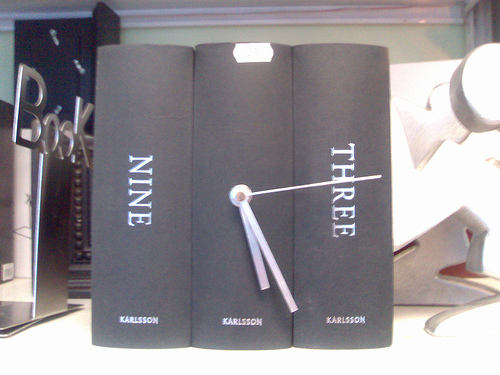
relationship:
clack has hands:
[224, 169, 293, 258] [203, 173, 308, 273]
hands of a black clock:
[203, 173, 308, 273] [91, 43, 393, 345]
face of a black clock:
[185, 161, 314, 240] [91, 43, 393, 345]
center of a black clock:
[203, 126, 296, 325] [91, 43, 393, 345]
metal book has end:
[85, 45, 216, 267] [105, 122, 197, 198]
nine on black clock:
[119, 145, 169, 240] [91, 43, 393, 345]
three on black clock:
[318, 140, 364, 240] [91, 43, 393, 345]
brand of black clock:
[193, 181, 346, 241] [91, 43, 393, 345]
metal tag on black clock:
[198, 302, 276, 341] [91, 43, 393, 345]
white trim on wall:
[393, 50, 498, 103] [393, 27, 433, 49]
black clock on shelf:
[91, 43, 393, 345] [60, 262, 464, 339]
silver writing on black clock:
[119, 145, 169, 240] [91, 43, 393, 345]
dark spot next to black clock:
[153, 56, 237, 119] [91, 43, 393, 345]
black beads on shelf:
[72, 280, 331, 341] [60, 262, 464, 339]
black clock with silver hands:
[145, 69, 283, 165] [224, 169, 293, 258]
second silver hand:
[236, 197, 286, 272] [229, 185, 278, 262]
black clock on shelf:
[145, 69, 283, 165] [60, 262, 464, 339]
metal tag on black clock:
[222, 318, 262, 326] [91, 43, 393, 345]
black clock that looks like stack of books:
[91, 43, 393, 345] [100, 46, 356, 183]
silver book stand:
[394, 64, 499, 234] [393, 187, 465, 288]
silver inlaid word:
[394, 64, 499, 234] [318, 140, 364, 240]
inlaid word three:
[306, 113, 368, 237] [318, 140, 364, 240]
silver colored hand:
[394, 64, 499, 234] [241, 203, 298, 313]